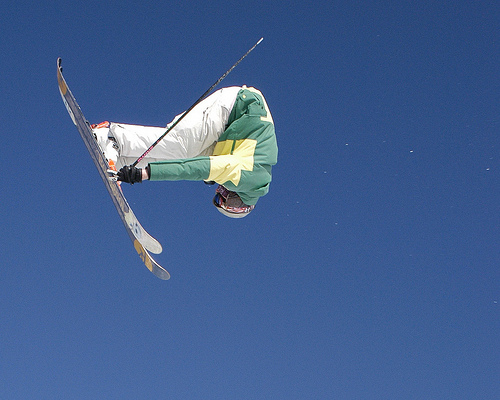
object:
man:
[89, 83, 279, 220]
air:
[0, 0, 499, 399]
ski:
[55, 57, 171, 281]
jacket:
[148, 83, 278, 206]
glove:
[115, 165, 142, 185]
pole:
[127, 35, 265, 169]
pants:
[90, 85, 243, 170]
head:
[212, 186, 255, 219]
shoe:
[90, 119, 110, 141]